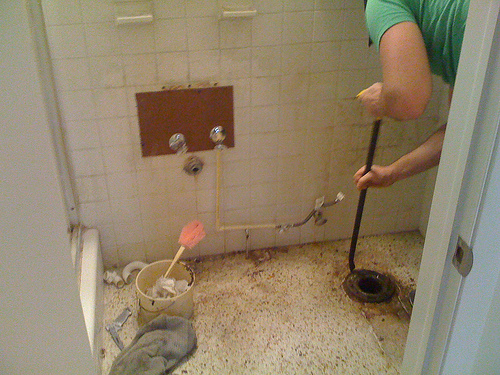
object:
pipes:
[101, 269, 116, 287]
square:
[134, 85, 235, 159]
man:
[352, 0, 471, 190]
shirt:
[364, 0, 469, 86]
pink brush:
[163, 219, 208, 277]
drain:
[340, 266, 398, 305]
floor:
[99, 232, 441, 374]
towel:
[106, 313, 197, 374]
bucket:
[134, 258, 197, 330]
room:
[0, 0, 499, 373]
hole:
[344, 266, 395, 303]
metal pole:
[347, 119, 382, 274]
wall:
[38, 0, 445, 271]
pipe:
[208, 126, 346, 233]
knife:
[105, 305, 132, 351]